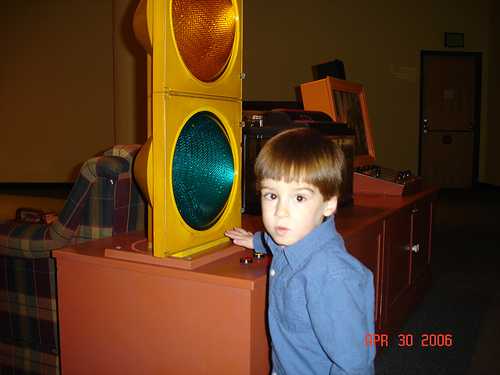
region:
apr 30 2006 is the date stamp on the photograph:
[363, 332, 454, 353]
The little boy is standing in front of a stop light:
[221, 124, 386, 371]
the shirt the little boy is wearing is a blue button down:
[228, 228, 396, 373]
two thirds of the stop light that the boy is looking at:
[108, 1, 263, 270]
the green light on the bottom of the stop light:
[155, 92, 247, 244]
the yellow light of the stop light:
[144, 0, 244, 100]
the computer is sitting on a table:
[296, 76, 430, 197]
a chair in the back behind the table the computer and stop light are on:
[3, 133, 140, 374]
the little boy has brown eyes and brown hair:
[222, 115, 384, 370]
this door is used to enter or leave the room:
[422, 50, 484, 188]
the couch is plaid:
[5, 135, 151, 313]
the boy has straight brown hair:
[249, 115, 345, 219]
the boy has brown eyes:
[258, 183, 313, 208]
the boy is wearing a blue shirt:
[251, 214, 374, 374]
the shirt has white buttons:
[261, 256, 281, 282]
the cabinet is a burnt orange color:
[53, 232, 278, 373]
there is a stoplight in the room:
[121, 8, 258, 263]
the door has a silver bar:
[413, 43, 485, 190]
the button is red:
[237, 251, 254, 266]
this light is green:
[157, 99, 239, 236]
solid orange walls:
[73, 300, 244, 347]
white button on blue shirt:
[260, 265, 292, 297]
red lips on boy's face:
[263, 220, 327, 247]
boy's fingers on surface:
[212, 215, 276, 261]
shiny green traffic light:
[160, 98, 247, 208]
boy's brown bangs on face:
[247, 135, 337, 185]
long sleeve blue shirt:
[248, 236, 412, 366]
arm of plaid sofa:
[45, 146, 145, 228]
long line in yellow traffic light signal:
[153, 80, 268, 112]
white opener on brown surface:
[402, 231, 439, 261]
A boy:
[188, 91, 387, 362]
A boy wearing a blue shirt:
[216, 106, 371, 373]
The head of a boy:
[244, 109, 345, 262]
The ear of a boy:
[322, 156, 348, 239]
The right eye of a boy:
[262, 175, 279, 207]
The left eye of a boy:
[290, 175, 310, 215]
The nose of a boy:
[270, 199, 293, 220]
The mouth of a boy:
[265, 222, 297, 242]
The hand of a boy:
[217, 202, 262, 265]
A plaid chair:
[8, 124, 132, 263]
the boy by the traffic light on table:
[244, 128, 405, 369]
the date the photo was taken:
[359, 332, 487, 347]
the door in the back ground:
[414, 46, 496, 168]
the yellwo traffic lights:
[115, 26, 245, 256]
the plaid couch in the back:
[34, 123, 134, 223]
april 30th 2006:
[366, 330, 448, 364]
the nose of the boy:
[271, 200, 293, 215]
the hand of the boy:
[223, 215, 270, 253]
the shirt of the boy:
[276, 263, 404, 366]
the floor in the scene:
[398, 246, 460, 372]